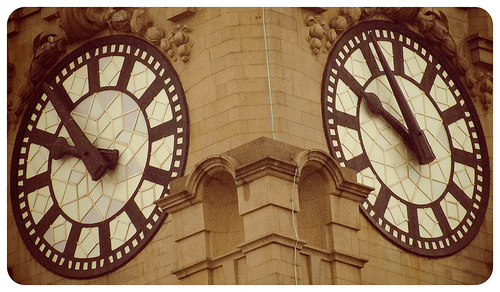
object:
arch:
[181, 151, 243, 194]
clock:
[9, 33, 193, 277]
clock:
[317, 19, 490, 260]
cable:
[260, 8, 279, 139]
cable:
[289, 153, 305, 283]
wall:
[8, 7, 266, 285]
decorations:
[163, 24, 194, 63]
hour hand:
[358, 88, 422, 157]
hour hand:
[34, 135, 122, 173]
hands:
[37, 81, 115, 183]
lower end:
[85, 162, 113, 181]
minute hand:
[367, 31, 437, 163]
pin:
[80, 149, 93, 157]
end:
[93, 146, 123, 173]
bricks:
[198, 110, 236, 133]